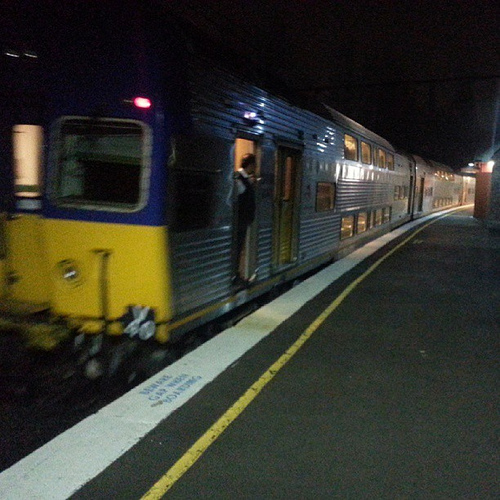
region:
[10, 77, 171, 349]
blue and yellow front of train car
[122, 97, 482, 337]
long silver train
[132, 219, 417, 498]
yellow stripe along tracks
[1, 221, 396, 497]
white stripe along tracks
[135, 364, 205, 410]
blue writing on platform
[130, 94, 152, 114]
red safety light on front of train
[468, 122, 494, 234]
light shining from station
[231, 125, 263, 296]
engineer standing at open train door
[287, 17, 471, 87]
black night sky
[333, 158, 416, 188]
reflection of lights on side of train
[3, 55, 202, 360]
front of train is blue and yellow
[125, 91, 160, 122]
red light on corner of train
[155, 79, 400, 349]
side of train car is silver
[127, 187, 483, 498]
yellow line on road beside train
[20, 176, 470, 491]
white line beside yellow line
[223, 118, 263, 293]
person standing in doorway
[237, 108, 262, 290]
person holding door open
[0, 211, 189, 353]
lower half of train is yellow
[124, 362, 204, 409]
warning on ground near platform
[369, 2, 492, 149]
sky is dark black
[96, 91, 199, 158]
The light is on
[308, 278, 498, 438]
The ground is dark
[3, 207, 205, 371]
The bottom of the train is yellow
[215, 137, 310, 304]
A person is standing in the doorway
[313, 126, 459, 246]
The train has windows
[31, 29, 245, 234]
The top of the train is blue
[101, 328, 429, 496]
The line on the ground is yellow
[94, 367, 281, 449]
The white part of the ground has writing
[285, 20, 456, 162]
The sky is dark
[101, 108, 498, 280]
The train is moving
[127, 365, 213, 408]
words on platform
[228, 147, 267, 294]
conductor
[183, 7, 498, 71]
dark sky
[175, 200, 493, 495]
zero passengers waiting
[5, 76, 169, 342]
front of train is yellow and blue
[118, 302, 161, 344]
lettering on front of train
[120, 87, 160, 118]
red light on front train car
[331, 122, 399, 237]
two layers of windows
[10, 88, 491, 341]
three train cars hooked together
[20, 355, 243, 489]
white edge of platform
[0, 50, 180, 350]
The head of the train is blue and yellow.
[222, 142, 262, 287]
A man standing at the door of the train.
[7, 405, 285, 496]
The border of the platform has white and yellow stripes.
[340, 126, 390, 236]
The train has two levels.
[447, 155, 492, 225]
Light brightens the platform.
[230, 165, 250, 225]
The man is wearing a dark vest.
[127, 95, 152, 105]
Small red light at the head of the train.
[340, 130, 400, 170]
Passengers are seated next to the windows.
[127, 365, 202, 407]
Blue writting on the white part of the platform.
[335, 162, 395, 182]
Reflection of the bright light.